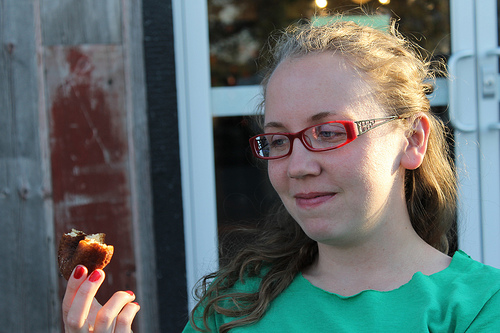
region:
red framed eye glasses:
[246, 115, 359, 160]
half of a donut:
[51, 226, 121, 275]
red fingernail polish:
[67, 263, 105, 284]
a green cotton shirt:
[182, 250, 497, 331]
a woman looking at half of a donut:
[46, 14, 499, 331]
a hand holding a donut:
[54, 225, 149, 330]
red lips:
[288, 187, 342, 213]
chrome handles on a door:
[441, 43, 498, 136]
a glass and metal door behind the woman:
[164, 0, 498, 320]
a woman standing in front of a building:
[157, 18, 492, 331]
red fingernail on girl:
[88, 270, 109, 285]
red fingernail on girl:
[68, 264, 80, 281]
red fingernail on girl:
[124, 290, 135, 296]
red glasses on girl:
[236, 125, 368, 156]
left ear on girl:
[397, 115, 430, 169]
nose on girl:
[281, 147, 326, 180]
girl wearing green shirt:
[216, 242, 498, 330]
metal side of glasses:
[354, 114, 406, 127]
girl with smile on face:
[282, 183, 344, 213]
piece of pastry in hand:
[49, 230, 145, 331]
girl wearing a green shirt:
[62, 22, 497, 327]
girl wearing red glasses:
[61, 25, 493, 321]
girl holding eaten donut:
[55, 20, 496, 325]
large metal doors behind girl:
[173, 1, 495, 331]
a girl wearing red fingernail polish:
[60, 5, 497, 326]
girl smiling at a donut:
[60, 21, 495, 327]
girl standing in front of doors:
[57, 25, 494, 327]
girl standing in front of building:
[49, 22, 486, 327]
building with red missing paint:
[1, 0, 498, 327]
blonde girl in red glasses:
[243, 34, 456, 260]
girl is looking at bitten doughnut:
[47, 185, 135, 311]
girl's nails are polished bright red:
[72, 256, 134, 326]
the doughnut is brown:
[59, 195, 130, 297]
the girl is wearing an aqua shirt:
[225, 250, 485, 330]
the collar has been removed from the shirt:
[256, 240, 464, 291]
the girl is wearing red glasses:
[203, 75, 394, 178]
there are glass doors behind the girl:
[425, 25, 498, 203]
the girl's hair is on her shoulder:
[181, 161, 323, 326]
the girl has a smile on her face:
[266, 170, 345, 237]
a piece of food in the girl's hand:
[37, 213, 145, 293]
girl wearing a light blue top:
[167, 239, 492, 331]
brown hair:
[136, 29, 482, 331]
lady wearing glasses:
[236, 94, 433, 172]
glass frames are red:
[236, 99, 410, 184]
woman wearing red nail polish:
[51, 256, 178, 331]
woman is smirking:
[266, 179, 380, 225]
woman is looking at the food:
[236, 7, 491, 316]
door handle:
[431, 36, 488, 152]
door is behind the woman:
[165, 0, 496, 285]